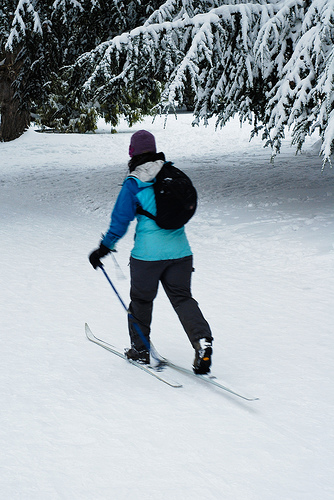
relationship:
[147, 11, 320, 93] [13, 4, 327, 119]
snow on tree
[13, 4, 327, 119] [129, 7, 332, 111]
tree has branches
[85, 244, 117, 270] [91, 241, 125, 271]
glove on hand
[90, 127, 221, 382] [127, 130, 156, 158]
skier wearing hat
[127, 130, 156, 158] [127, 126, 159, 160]
hat on head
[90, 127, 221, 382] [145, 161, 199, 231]
skier has backpack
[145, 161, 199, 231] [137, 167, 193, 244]
backpack on back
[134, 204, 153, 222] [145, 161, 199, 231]
strap attached to backpack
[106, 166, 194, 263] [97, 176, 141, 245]
coat has sleeve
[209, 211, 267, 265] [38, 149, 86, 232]
tracks on snow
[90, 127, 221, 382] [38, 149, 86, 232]
skier on snow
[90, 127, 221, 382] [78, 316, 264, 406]
skier wearing skis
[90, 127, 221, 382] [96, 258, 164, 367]
skier holding pole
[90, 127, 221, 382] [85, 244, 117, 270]
skier wearing glove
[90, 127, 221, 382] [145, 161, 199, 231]
skier carrying backpack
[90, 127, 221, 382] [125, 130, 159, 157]
skier wearing cap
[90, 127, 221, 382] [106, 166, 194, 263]
skier wearing coat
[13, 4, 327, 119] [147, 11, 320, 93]
tree has snow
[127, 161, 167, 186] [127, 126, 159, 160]
hood behind head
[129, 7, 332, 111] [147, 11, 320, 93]
branches have snow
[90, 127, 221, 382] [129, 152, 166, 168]
skier has neck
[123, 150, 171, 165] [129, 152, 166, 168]
collar around neck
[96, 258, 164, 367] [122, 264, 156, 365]
pole outside of leg